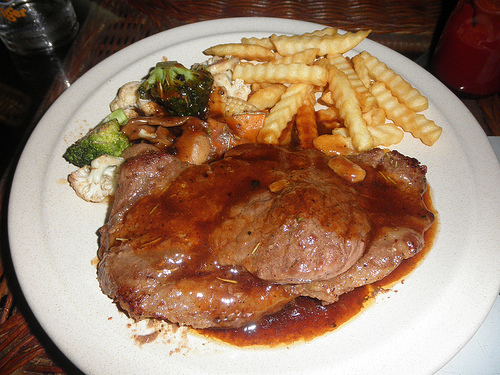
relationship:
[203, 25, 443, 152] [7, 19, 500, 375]
fries on plate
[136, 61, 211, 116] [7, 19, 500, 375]
broccoli on plate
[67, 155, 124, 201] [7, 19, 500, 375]
cauliflower on plate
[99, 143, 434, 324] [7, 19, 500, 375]
meat on plate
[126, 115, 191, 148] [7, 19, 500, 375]
mushroom on plate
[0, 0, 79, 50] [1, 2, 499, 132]
glass on table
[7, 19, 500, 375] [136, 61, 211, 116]
plate has broccoli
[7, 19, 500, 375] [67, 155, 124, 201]
plate has cauliflower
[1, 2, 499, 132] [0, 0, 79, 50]
table has glass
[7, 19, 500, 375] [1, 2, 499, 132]
plate on table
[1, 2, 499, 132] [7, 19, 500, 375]
table with plate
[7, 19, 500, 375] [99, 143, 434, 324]
plate has meat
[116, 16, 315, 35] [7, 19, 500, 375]
edge of plate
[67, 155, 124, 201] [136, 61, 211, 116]
cauliflower with broccoli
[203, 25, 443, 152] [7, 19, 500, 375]
fries are on plate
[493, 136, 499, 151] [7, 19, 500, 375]
napkin under plate